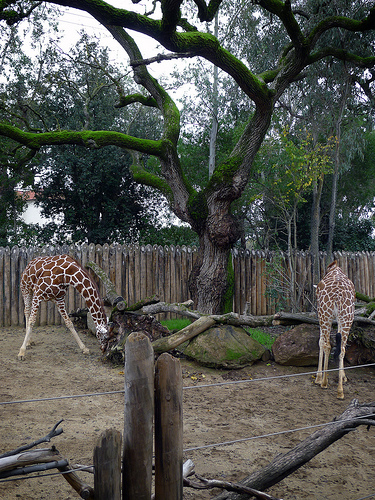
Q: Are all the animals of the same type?
A: Yes, all the animals are giraffes.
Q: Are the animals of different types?
A: No, all the animals are giraffes.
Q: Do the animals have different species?
A: No, all the animals are giraffes.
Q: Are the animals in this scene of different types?
A: No, all the animals are giraffes.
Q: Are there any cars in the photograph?
A: No, there are no cars.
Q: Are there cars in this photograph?
A: No, there are no cars.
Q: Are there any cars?
A: No, there are no cars.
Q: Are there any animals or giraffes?
A: Yes, there is a giraffe.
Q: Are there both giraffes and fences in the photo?
A: Yes, there are both a giraffe and a fence.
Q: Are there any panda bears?
A: No, there are no panda bears.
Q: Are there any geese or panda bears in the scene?
A: No, there are no panda bears or geese.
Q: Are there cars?
A: No, there are no cars.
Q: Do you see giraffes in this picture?
A: Yes, there is a giraffe.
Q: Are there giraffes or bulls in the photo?
A: Yes, there is a giraffe.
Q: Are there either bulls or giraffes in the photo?
A: Yes, there is a giraffe.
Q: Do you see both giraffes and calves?
A: No, there is a giraffe but no calves.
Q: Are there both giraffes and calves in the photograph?
A: No, there is a giraffe but no calves.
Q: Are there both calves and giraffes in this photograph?
A: No, there is a giraffe but no calves.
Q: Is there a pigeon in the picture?
A: No, there are no pigeons.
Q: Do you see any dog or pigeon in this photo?
A: No, there are no pigeons or dogs.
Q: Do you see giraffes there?
A: Yes, there is a giraffe.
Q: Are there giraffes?
A: Yes, there is a giraffe.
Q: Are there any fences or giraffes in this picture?
A: Yes, there is a giraffe.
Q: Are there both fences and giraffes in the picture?
A: Yes, there are both a giraffe and a fence.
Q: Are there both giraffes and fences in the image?
A: Yes, there are both a giraffe and a fence.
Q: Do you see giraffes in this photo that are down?
A: Yes, there is a giraffe that is down.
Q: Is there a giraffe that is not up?
A: Yes, there is a giraffe that is down.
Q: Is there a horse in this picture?
A: No, there are no horses.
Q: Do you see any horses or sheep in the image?
A: No, there are no horses or sheep.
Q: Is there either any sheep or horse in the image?
A: No, there are no horses or sheep.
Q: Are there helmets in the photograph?
A: No, there are no helmets.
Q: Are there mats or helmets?
A: No, there are no helmets or mats.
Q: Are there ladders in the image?
A: No, there are no ladders.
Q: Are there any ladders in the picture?
A: No, there are no ladders.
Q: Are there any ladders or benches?
A: No, there are no ladders or benches.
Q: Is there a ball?
A: No, there are no balls.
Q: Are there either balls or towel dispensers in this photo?
A: No, there are no balls or towel dispensers.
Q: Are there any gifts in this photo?
A: No, there are no gifts.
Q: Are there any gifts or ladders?
A: No, there are no gifts or ladders.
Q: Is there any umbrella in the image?
A: No, there are no umbrellas.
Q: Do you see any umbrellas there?
A: No, there are no umbrellas.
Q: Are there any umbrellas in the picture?
A: No, there are no umbrellas.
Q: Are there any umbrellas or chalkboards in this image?
A: No, there are no umbrellas or chalkboards.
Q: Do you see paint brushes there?
A: No, there are no paint brushes.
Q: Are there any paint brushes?
A: No, there are no paint brushes.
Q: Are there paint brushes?
A: No, there are no paint brushes.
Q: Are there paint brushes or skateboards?
A: No, there are no paint brushes or skateboards.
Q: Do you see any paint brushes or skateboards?
A: No, there are no paint brushes or skateboards.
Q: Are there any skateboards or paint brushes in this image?
A: No, there are no paint brushes or skateboards.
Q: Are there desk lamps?
A: No, there are no desk lamps.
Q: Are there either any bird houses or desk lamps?
A: No, there are no desk lamps or bird houses.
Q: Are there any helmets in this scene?
A: No, there are no helmets.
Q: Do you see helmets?
A: No, there are no helmets.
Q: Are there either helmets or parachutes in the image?
A: No, there are no helmets or parachutes.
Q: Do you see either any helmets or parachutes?
A: No, there are no helmets or parachutes.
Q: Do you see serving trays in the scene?
A: No, there are no serving trays.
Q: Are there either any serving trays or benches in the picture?
A: No, there are no serving trays or benches.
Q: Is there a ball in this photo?
A: No, there are no balls.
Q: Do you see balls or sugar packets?
A: No, there are no balls or sugar packets.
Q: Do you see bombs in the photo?
A: No, there are no bombs.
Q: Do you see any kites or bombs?
A: No, there are no bombs or kites.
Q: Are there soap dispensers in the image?
A: No, there are no soap dispensers.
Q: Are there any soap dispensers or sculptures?
A: No, there are no soap dispensers or sculptures.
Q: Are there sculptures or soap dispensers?
A: No, there are no soap dispensers or sculptures.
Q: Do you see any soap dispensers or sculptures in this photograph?
A: No, there are no soap dispensers or sculptures.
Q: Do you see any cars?
A: No, there are no cars.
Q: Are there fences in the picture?
A: Yes, there is a fence.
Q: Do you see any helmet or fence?
A: Yes, there is a fence.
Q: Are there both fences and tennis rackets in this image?
A: No, there is a fence but no rackets.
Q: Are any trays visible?
A: No, there are no trays.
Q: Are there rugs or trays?
A: No, there are no trays or rugs.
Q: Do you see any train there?
A: No, there are no trains.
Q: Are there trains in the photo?
A: No, there are no trains.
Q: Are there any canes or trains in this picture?
A: No, there are no trains or canes.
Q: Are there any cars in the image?
A: No, there are no cars.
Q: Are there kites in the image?
A: No, there are no kites.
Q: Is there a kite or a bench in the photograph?
A: No, there are no kites or benches.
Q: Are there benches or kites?
A: No, there are no kites or benches.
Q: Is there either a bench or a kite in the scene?
A: No, there are no kites or benches.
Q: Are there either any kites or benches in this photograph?
A: No, there are no kites or benches.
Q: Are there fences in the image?
A: Yes, there is a fence.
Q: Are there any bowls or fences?
A: Yes, there is a fence.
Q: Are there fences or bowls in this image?
A: Yes, there is a fence.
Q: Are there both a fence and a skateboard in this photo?
A: No, there is a fence but no skateboards.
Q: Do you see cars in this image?
A: No, there are no cars.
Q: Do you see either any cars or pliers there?
A: No, there are no cars or pliers.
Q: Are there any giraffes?
A: Yes, there is a giraffe.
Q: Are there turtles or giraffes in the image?
A: Yes, there is a giraffe.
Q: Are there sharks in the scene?
A: No, there are no sharks.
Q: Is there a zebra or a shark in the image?
A: No, there are no sharks or zebras.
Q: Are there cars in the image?
A: No, there are no cars.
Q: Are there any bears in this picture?
A: No, there are no bears.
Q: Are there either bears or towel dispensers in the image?
A: No, there are no bears or towel dispensers.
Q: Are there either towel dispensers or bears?
A: No, there are no bears or towel dispensers.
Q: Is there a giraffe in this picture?
A: Yes, there are giraffes.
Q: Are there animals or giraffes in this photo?
A: Yes, there are giraffes.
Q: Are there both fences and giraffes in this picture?
A: Yes, there are both giraffes and a fence.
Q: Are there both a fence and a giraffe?
A: Yes, there are both a giraffe and a fence.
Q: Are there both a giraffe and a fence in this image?
A: Yes, there are both a giraffe and a fence.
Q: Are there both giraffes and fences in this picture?
A: Yes, there are both giraffes and a fence.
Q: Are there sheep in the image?
A: No, there are no sheep.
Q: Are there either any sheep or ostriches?
A: No, there are no sheep or ostriches.